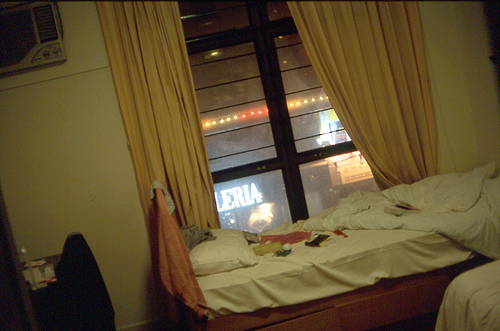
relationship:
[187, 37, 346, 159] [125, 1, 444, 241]
bar on window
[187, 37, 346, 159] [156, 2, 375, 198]
bar on window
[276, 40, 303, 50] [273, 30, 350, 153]
bar on window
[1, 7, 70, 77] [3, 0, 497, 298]
conditioner on wall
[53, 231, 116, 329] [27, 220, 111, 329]
chair hanging on chair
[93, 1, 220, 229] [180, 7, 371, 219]
curtain on bar window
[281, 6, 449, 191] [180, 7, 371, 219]
curtain on bar window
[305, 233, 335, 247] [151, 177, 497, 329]
book on bed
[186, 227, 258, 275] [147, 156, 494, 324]
pillow on bed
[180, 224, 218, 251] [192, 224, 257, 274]
grey shirt on pillow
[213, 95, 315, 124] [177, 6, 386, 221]
lights outside window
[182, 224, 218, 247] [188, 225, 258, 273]
grey shirt on pillow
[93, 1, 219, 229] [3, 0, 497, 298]
curtain on wall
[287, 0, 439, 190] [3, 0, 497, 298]
curtain on wall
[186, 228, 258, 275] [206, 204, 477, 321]
pillow on bed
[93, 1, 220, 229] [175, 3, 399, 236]
curtain around window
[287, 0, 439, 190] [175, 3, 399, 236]
curtain around window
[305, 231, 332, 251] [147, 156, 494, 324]
book on bed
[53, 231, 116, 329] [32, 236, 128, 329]
chair on chair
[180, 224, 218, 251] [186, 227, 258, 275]
grey shirt on pillow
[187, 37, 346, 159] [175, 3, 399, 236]
bar on window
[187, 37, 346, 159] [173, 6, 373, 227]
bar on window